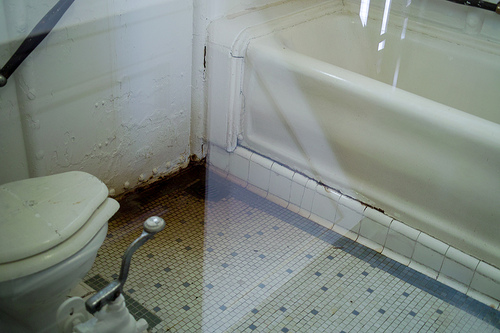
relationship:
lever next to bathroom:
[87, 208, 167, 315] [0, 0, 500, 331]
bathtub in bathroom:
[203, 4, 495, 314] [2, 3, 481, 331]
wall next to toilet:
[4, 6, 204, 197] [1, 167, 122, 312]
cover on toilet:
[0, 169, 108, 264] [1, 167, 122, 312]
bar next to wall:
[2, 4, 78, 83] [4, 6, 204, 197]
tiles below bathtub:
[66, 181, 480, 331] [202, 0, 499, 271]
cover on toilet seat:
[1, 166, 112, 274] [1, 166, 124, 332]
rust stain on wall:
[112, 150, 214, 207] [4, 0, 198, 218]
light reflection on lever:
[89, 279, 125, 309] [84, 215, 167, 315]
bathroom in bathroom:
[0, 0, 500, 331] [2, 3, 481, 331]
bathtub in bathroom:
[202, 0, 499, 271] [2, 3, 481, 331]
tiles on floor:
[66, 181, 480, 331] [65, 166, 479, 327]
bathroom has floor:
[2, 3, 481, 331] [65, 166, 479, 327]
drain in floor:
[183, 174, 233, 204] [65, 166, 479, 327]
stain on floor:
[114, 164, 302, 277] [65, 166, 479, 327]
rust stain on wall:
[126, 158, 205, 198] [4, 0, 198, 218]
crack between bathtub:
[233, 136, 392, 218] [202, 0, 499, 271]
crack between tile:
[233, 136, 392, 218] [205, 133, 485, 306]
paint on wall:
[2, 2, 202, 210] [4, 0, 198, 218]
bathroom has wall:
[2, 3, 481, 331] [4, 0, 198, 218]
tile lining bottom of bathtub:
[202, 142, 484, 314] [202, 0, 499, 271]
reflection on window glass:
[193, 3, 414, 329] [3, 2, 479, 332]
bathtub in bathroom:
[202, 0, 499, 271] [0, 0, 500, 331]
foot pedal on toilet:
[83, 207, 166, 314] [2, 166, 166, 330]